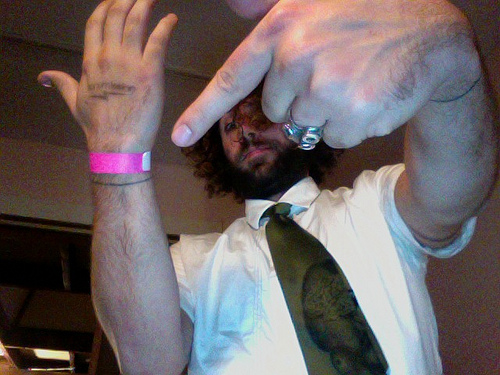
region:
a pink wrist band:
[78, 149, 162, 179]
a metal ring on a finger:
[282, 115, 323, 145]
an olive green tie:
[258, 207, 404, 374]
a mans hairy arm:
[40, 1, 184, 373]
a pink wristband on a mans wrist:
[38, 0, 175, 167]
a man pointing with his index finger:
[175, 0, 483, 163]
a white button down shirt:
[163, 158, 415, 373]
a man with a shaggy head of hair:
[193, 78, 331, 190]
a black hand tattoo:
[75, 78, 149, 107]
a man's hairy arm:
[38, 10, 199, 365]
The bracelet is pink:
[78, 137, 165, 177]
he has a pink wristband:
[77, 141, 163, 179]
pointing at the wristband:
[167, 10, 442, 150]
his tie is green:
[273, 213, 344, 338]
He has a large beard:
[232, 143, 296, 194]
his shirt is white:
[192, 170, 409, 368]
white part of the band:
[140, 143, 153, 173]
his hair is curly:
[188, 105, 326, 205]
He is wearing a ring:
[282, 113, 334, 148]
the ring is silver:
[280, 117, 341, 150]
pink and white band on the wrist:
[68, 150, 156, 173]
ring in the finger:
[274, 108, 324, 156]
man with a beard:
[219, 152, 311, 189]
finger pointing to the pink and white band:
[169, 10, 439, 160]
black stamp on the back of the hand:
[79, 73, 142, 102]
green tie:
[263, 208, 373, 374]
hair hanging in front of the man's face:
[231, 108, 251, 149]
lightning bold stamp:
[84, 89, 132, 103]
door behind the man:
[71, 326, 113, 373]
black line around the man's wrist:
[82, 171, 159, 193]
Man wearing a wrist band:
[81, 142, 161, 177]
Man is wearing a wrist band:
[82, 146, 159, 176]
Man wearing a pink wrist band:
[86, 145, 155, 175]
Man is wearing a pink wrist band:
[83, 144, 156, 177]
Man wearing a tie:
[259, 199, 393, 374]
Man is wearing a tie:
[257, 200, 397, 373]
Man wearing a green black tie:
[255, 200, 393, 372]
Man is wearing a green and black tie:
[256, 196, 392, 372]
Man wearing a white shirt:
[126, 165, 478, 373]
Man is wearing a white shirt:
[135, 156, 483, 373]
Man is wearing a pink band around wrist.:
[96, 137, 163, 174]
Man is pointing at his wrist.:
[160, 100, 232, 169]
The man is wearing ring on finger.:
[286, 107, 326, 154]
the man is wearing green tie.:
[273, 217, 382, 357]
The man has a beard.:
[208, 153, 312, 203]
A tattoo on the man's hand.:
[69, 75, 162, 108]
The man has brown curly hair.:
[187, 135, 245, 208]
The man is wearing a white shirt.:
[196, 205, 423, 327]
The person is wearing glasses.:
[218, 114, 276, 140]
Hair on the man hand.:
[401, 36, 478, 96]